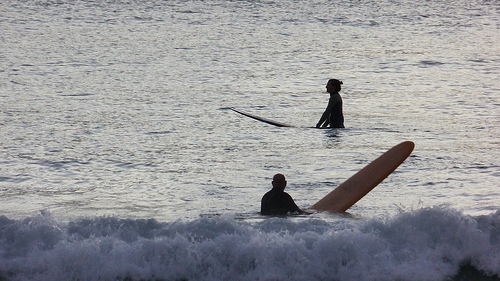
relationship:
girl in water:
[290, 66, 374, 129] [2, 2, 486, 279]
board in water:
[227, 105, 294, 126] [177, 63, 467, 210]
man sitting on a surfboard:
[258, 173, 307, 215] [311, 141, 419, 219]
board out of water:
[309, 141, 415, 213] [2, 2, 486, 279]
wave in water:
[7, 151, 500, 281] [2, 2, 486, 279]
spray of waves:
[5, 211, 498, 274] [14, 214, 461, 273]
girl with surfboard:
[315, 79, 345, 129] [225, 100, 331, 130]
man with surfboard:
[258, 173, 307, 215] [295, 129, 415, 225]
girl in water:
[315, 79, 345, 129] [2, 2, 486, 279]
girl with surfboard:
[315, 79, 345, 129] [233, 107, 310, 128]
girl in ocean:
[315, 79, 345, 129] [3, 4, 467, 273]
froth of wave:
[91, 247, 121, 271] [7, 200, 451, 280]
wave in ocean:
[7, 200, 451, 280] [3, 4, 467, 273]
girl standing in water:
[315, 79, 345, 129] [2, 2, 486, 279]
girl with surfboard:
[315, 79, 345, 129] [208, 92, 316, 134]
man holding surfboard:
[258, 173, 307, 215] [301, 140, 416, 227]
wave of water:
[7, 151, 500, 281] [3, 4, 495, 210]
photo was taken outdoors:
[0, 0, 497, 280] [0, 1, 499, 279]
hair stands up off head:
[332, 76, 343, 90] [320, 77, 343, 93]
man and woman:
[262, 173, 309, 214] [315, 78, 342, 128]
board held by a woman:
[227, 105, 294, 126] [277, 71, 369, 148]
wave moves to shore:
[7, 151, 500, 281] [13, 230, 493, 278]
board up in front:
[224, 98, 291, 133] [231, 95, 297, 128]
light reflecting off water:
[343, 15, 497, 56] [2, 2, 486, 279]